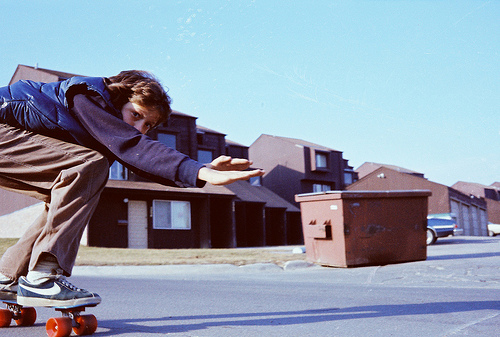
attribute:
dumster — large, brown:
[260, 158, 460, 276]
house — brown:
[8, 65, 300, 247]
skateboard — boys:
[3, 290, 103, 333]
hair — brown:
[104, 65, 172, 110]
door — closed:
[120, 193, 152, 253]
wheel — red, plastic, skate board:
[16, 303, 37, 327]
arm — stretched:
[73, 92, 264, 184]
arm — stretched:
[112, 155, 254, 185]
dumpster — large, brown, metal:
[286, 188, 433, 270]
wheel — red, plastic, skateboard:
[21, 304, 72, 335]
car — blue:
[407, 189, 461, 287]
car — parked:
[425, 215, 463, 244]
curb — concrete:
[72, 260, 311, 276]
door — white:
[106, 176, 194, 254]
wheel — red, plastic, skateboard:
[45, 311, 73, 334]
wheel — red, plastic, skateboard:
[73, 308, 101, 334]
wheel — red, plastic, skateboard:
[16, 304, 38, 329]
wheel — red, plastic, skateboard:
[1, 301, 13, 331]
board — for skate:
[7, 265, 152, 331]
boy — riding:
[5, 54, 265, 335]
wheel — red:
[38, 307, 75, 335]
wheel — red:
[73, 317, 107, 335]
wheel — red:
[4, 293, 45, 327]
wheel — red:
[0, 300, 17, 335]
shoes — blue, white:
[7, 264, 101, 314]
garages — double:
[357, 165, 499, 250]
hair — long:
[110, 66, 167, 106]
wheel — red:
[1, 310, 13, 324]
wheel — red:
[16, 308, 32, 326]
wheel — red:
[43, 316, 70, 334]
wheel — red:
[76, 312, 95, 331]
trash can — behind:
[294, 188, 436, 271]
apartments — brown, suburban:
[283, 141, 330, 167]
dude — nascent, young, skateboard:
[3, 63, 265, 308]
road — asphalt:
[1, 263, 483, 335]